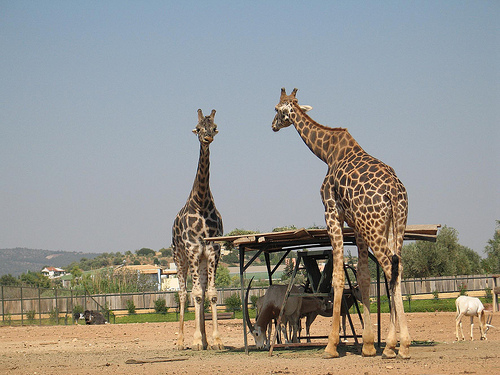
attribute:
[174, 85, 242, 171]
giraffe — curious, large, looking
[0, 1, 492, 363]
camera — blue, clear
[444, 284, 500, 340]
goat — white, grazing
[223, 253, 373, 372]
goats — standing, in shade, grazing, white, enclosed, outdoor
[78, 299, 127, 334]
black cow — laying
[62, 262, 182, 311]
trees — green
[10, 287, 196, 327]
fence — wooden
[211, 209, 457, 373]
structure — wooden, shaded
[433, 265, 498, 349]
gazelle — grazing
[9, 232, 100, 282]
hills — green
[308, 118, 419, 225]
bodys — spotted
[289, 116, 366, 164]
neck — bending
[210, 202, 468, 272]
shade — wooden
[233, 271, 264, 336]
horn — upward, curved, long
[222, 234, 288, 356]
supports — metal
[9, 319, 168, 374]
ground — dry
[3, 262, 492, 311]
wooden fence — enclosed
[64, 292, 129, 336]
animal — large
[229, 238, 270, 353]
frame — metallic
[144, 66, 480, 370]
giraffes — brown, white